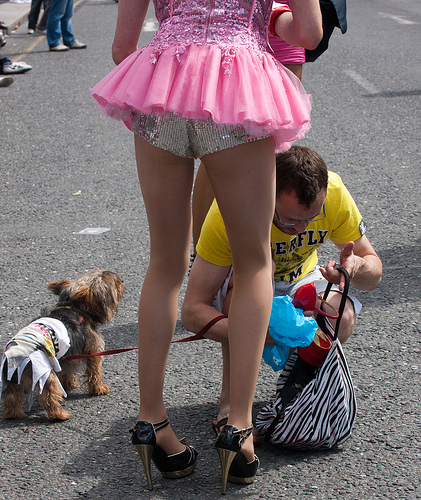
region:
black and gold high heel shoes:
[210, 411, 269, 498]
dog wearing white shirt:
[7, 246, 127, 432]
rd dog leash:
[56, 298, 312, 359]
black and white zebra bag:
[273, 294, 357, 497]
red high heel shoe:
[285, 270, 345, 379]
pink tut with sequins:
[89, 0, 380, 111]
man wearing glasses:
[274, 194, 350, 233]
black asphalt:
[11, 115, 92, 223]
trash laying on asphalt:
[66, 212, 138, 269]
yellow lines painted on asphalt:
[4, 5, 73, 97]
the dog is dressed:
[25, 289, 196, 419]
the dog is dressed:
[4, 244, 142, 422]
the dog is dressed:
[41, 265, 118, 366]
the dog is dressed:
[34, 310, 141, 433]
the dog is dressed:
[14, 240, 192, 499]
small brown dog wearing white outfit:
[9, 265, 124, 420]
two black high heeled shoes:
[113, 409, 273, 493]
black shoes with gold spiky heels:
[123, 416, 261, 495]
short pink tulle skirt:
[97, 26, 312, 220]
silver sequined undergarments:
[110, 106, 292, 161]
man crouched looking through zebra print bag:
[275, 151, 368, 456]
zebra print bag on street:
[260, 353, 359, 479]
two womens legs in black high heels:
[121, 157, 272, 499]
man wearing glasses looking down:
[278, 150, 330, 245]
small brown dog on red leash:
[6, 262, 238, 424]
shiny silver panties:
[113, 98, 261, 154]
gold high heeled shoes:
[87, 407, 269, 491]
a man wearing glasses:
[226, 139, 335, 236]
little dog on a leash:
[9, 258, 123, 440]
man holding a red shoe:
[253, 276, 347, 364]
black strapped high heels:
[96, 416, 265, 490]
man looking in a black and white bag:
[247, 264, 377, 466]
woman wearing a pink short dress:
[90, 5, 337, 161]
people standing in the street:
[0, 0, 88, 83]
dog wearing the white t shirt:
[0, 316, 84, 390]